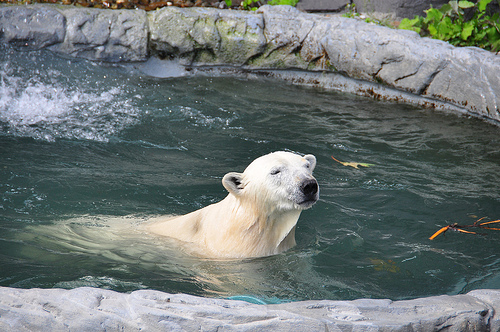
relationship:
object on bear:
[225, 290, 287, 306] [51, 151, 320, 263]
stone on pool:
[48, 4, 458, 80] [5, 2, 499, 332]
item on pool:
[402, 203, 497, 277] [5, 2, 499, 332]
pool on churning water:
[5, 2, 499, 329] [4, 62, 154, 144]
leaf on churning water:
[331, 155, 376, 169] [0, 62, 138, 141]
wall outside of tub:
[294, 2, 441, 34] [1, 5, 498, 329]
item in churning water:
[429, 216, 499, 240] [0, 62, 138, 141]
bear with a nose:
[35, 155, 393, 305] [301, 179, 318, 194]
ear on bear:
[216, 171, 246, 194] [51, 151, 320, 263]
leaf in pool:
[326, 151, 376, 179] [5, 2, 499, 332]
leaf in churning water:
[331, 155, 376, 169] [0, 62, 138, 141]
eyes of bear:
[270, 159, 312, 176] [51, 151, 320, 263]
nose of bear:
[295, 178, 321, 196] [51, 151, 320, 263]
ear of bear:
[221, 172, 243, 198] [51, 151, 320, 263]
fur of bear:
[150, 143, 323, 258] [51, 151, 320, 263]